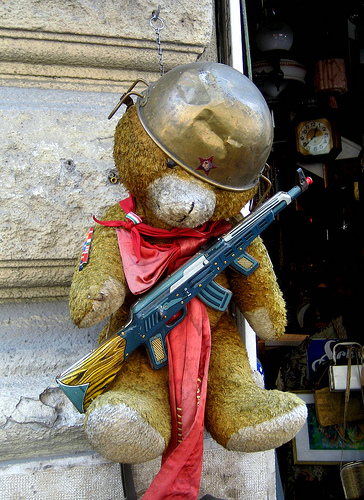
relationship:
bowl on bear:
[107, 60, 276, 193] [71, 101, 309, 450]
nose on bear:
[168, 201, 200, 224] [63, 57, 307, 466]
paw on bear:
[67, 276, 127, 328] [68, 60, 309, 464]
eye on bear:
[164, 161, 177, 174] [71, 101, 309, 450]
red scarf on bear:
[86, 197, 214, 497] [63, 57, 307, 466]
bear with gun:
[68, 60, 309, 464] [46, 158, 326, 420]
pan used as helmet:
[107, 61, 272, 212] [108, 54, 278, 192]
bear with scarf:
[68, 60, 309, 464] [117, 228, 229, 498]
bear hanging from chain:
[68, 60, 309, 464] [143, 8, 174, 75]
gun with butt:
[54, 167, 317, 416] [67, 332, 130, 414]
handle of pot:
[107, 78, 155, 117] [107, 62, 274, 210]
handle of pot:
[252, 157, 273, 211] [107, 62, 274, 210]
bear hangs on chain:
[68, 60, 309, 464] [149, 13, 166, 75]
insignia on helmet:
[197, 156, 216, 174] [114, 60, 267, 190]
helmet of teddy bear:
[114, 60, 267, 190] [71, 117, 309, 464]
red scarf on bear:
[89, 197, 220, 500] [71, 101, 309, 450]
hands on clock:
[292, 114, 333, 154] [288, 108, 343, 165]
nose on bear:
[168, 201, 200, 224] [71, 101, 309, 450]